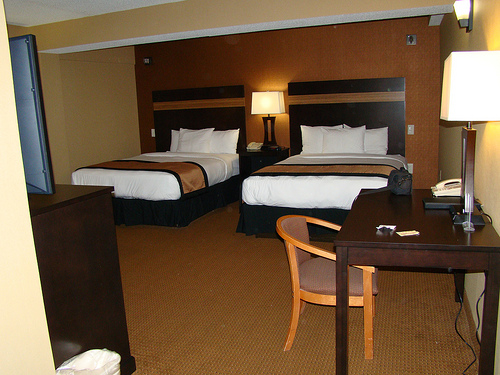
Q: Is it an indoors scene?
A: Yes, it is indoors.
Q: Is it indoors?
A: Yes, it is indoors.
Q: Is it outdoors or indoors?
A: It is indoors.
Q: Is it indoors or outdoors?
A: It is indoors.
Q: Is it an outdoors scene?
A: No, it is indoors.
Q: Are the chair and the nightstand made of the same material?
A: Yes, both the chair and the nightstand are made of wood.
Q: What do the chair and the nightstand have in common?
A: The material, both the chair and the nightstand are wooden.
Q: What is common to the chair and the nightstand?
A: The material, both the chair and the nightstand are wooden.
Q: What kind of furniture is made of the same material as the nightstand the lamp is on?
A: The chair is made of the same material as the nightstand.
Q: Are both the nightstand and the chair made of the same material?
A: Yes, both the nightstand and the chair are made of wood.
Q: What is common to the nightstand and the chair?
A: The material, both the nightstand and the chair are wooden.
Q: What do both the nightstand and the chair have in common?
A: The material, both the nightstand and the chair are wooden.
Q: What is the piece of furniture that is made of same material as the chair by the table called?
A: The piece of furniture is a nightstand.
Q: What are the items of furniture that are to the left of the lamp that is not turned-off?
A: The pieces of furniture are beds.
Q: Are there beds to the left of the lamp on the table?
A: Yes, there are beds to the left of the lamp.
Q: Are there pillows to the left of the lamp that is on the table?
A: No, there are beds to the left of the lamp.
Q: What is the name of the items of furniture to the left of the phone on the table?
A: The pieces of furniture are beds.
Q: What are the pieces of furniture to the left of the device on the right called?
A: The pieces of furniture are beds.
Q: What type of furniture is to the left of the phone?
A: The pieces of furniture are beds.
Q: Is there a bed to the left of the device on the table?
A: Yes, there are beds to the left of the telephone.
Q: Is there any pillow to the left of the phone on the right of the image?
A: No, there are beds to the left of the phone.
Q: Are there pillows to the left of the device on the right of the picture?
A: No, there are beds to the left of the phone.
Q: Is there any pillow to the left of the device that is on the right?
A: No, there are beds to the left of the phone.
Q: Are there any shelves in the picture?
A: No, there are no shelves.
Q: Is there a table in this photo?
A: Yes, there is a table.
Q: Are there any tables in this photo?
A: Yes, there is a table.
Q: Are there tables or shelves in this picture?
A: Yes, there is a table.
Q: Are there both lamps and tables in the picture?
A: Yes, there are both a table and a lamp.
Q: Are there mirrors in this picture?
A: No, there are no mirrors.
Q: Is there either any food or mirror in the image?
A: No, there are no mirrors or food.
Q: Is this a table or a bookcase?
A: This is a table.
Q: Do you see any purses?
A: Yes, there is a purse.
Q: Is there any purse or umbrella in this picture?
A: Yes, there is a purse.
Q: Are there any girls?
A: No, there are no girls.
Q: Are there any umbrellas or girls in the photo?
A: No, there are no girls or umbrellas.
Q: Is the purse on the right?
A: Yes, the purse is on the right of the image.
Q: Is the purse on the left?
A: No, the purse is on the right of the image.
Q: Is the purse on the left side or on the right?
A: The purse is on the right of the image.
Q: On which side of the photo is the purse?
A: The purse is on the right of the image.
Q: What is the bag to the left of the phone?
A: The bag is a purse.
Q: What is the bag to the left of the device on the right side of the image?
A: The bag is a purse.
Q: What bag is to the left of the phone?
A: The bag is a purse.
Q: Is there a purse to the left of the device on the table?
A: Yes, there is a purse to the left of the phone.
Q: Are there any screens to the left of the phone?
A: No, there is a purse to the left of the phone.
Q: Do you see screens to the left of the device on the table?
A: No, there is a purse to the left of the phone.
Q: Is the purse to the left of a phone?
A: Yes, the purse is to the left of a phone.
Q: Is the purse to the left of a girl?
A: No, the purse is to the left of a phone.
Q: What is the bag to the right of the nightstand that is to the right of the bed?
A: The bag is a purse.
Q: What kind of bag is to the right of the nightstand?
A: The bag is a purse.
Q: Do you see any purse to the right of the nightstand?
A: Yes, there is a purse to the right of the nightstand.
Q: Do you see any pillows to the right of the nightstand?
A: No, there is a purse to the right of the nightstand.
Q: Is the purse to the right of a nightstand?
A: Yes, the purse is to the right of a nightstand.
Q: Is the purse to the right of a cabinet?
A: No, the purse is to the right of a nightstand.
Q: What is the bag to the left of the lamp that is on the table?
A: The bag is a purse.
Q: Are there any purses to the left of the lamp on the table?
A: Yes, there is a purse to the left of the lamp.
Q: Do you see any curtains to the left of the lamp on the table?
A: No, there is a purse to the left of the lamp.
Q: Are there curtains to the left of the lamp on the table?
A: No, there is a purse to the left of the lamp.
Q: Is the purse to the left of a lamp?
A: Yes, the purse is to the left of a lamp.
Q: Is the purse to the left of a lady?
A: No, the purse is to the left of a lamp.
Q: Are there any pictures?
A: No, there are no pictures.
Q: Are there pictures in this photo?
A: No, there are no pictures.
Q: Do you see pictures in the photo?
A: No, there are no pictures.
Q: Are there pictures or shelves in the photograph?
A: No, there are no pictures or shelves.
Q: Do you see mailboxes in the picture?
A: No, there are no mailboxes.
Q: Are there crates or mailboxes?
A: No, there are no mailboxes or crates.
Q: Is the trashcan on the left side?
A: Yes, the trashcan is on the left of the image.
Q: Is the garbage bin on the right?
A: No, the garbage bin is on the left of the image.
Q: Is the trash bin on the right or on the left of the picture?
A: The trash bin is on the left of the image.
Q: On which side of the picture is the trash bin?
A: The trash bin is on the left of the image.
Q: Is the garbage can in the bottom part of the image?
A: Yes, the garbage can is in the bottom of the image.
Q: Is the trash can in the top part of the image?
A: No, the trash can is in the bottom of the image.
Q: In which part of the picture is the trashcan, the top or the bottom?
A: The trashcan is in the bottom of the image.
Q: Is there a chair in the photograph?
A: Yes, there is a chair.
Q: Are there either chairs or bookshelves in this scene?
A: Yes, there is a chair.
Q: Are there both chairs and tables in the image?
A: Yes, there are both a chair and a table.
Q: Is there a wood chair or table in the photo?
A: Yes, there is a wood chair.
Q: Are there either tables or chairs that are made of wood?
A: Yes, the chair is made of wood.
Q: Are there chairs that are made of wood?
A: Yes, there is a chair that is made of wood.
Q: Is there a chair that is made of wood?
A: Yes, there is a chair that is made of wood.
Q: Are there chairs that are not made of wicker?
A: Yes, there is a chair that is made of wood.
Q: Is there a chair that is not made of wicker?
A: Yes, there is a chair that is made of wood.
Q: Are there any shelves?
A: No, there are no shelves.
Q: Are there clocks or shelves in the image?
A: No, there are no shelves or clocks.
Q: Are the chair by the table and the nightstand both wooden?
A: Yes, both the chair and the nightstand are wooden.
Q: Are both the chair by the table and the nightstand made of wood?
A: Yes, both the chair and the nightstand are made of wood.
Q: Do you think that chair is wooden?
A: Yes, the chair is wooden.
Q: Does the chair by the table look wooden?
A: Yes, the chair is wooden.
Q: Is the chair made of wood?
A: Yes, the chair is made of wood.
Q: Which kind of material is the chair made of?
A: The chair is made of wood.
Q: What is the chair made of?
A: The chair is made of wood.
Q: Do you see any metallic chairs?
A: No, there is a chair but it is wooden.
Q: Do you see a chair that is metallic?
A: No, there is a chair but it is wooden.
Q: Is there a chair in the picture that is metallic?
A: No, there is a chair but it is wooden.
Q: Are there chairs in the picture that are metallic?
A: No, there is a chair but it is wooden.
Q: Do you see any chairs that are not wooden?
A: No, there is a chair but it is wooden.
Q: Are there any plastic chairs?
A: No, there is a chair but it is made of wood.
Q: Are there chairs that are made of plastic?
A: No, there is a chair but it is made of wood.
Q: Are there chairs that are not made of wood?
A: No, there is a chair but it is made of wood.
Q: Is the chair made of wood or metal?
A: The chair is made of wood.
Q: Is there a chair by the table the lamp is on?
A: Yes, there is a chair by the table.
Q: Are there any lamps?
A: Yes, there is a lamp.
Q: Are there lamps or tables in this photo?
A: Yes, there is a lamp.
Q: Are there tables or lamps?
A: Yes, there is a lamp.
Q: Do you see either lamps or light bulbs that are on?
A: Yes, the lamp is on.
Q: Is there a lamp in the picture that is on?
A: Yes, there is a lamp that is on.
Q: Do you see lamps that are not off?
A: Yes, there is a lamp that is on .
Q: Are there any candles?
A: No, there are no candles.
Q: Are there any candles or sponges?
A: No, there are no candles or sponges.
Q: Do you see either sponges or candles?
A: No, there are no candles or sponges.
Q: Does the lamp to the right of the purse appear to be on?
A: Yes, the lamp is on.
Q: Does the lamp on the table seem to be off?
A: No, the lamp is on.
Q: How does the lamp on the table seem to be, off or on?
A: The lamp is on.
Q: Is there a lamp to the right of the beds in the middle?
A: Yes, there is a lamp to the right of the beds.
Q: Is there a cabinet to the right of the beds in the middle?
A: No, there is a lamp to the right of the beds.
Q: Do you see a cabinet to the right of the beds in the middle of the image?
A: No, there is a lamp to the right of the beds.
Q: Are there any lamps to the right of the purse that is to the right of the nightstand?
A: Yes, there is a lamp to the right of the purse.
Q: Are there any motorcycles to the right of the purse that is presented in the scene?
A: No, there is a lamp to the right of the purse.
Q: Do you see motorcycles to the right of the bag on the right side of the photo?
A: No, there is a lamp to the right of the purse.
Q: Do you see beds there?
A: Yes, there is a bed.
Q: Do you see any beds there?
A: Yes, there is a bed.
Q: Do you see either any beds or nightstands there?
A: Yes, there is a bed.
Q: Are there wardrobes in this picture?
A: No, there are no wardrobes.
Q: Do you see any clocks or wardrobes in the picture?
A: No, there are no wardrobes or clocks.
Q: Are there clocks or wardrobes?
A: No, there are no wardrobes or clocks.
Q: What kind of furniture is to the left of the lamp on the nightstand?
A: The piece of furniture is a bed.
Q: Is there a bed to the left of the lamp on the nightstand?
A: Yes, there is a bed to the left of the lamp.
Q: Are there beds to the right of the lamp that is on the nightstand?
A: No, the bed is to the left of the lamp.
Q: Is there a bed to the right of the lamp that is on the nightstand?
A: No, the bed is to the left of the lamp.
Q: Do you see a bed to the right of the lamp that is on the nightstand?
A: No, the bed is to the left of the lamp.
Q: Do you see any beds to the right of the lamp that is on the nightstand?
A: No, the bed is to the left of the lamp.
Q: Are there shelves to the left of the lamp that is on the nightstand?
A: No, there is a bed to the left of the lamp.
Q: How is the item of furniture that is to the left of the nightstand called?
A: The piece of furniture is a bed.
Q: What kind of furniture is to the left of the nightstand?
A: The piece of furniture is a bed.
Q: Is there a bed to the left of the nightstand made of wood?
A: Yes, there is a bed to the left of the nightstand.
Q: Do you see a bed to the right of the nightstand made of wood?
A: No, the bed is to the left of the nightstand.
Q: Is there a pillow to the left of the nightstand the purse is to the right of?
A: No, there is a bed to the left of the nightstand.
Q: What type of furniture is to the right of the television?
A: The piece of furniture is a bed.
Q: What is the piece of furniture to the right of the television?
A: The piece of furniture is a bed.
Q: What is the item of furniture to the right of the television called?
A: The piece of furniture is a bed.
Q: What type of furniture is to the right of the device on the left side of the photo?
A: The piece of furniture is a bed.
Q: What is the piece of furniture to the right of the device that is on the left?
A: The piece of furniture is a bed.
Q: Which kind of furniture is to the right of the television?
A: The piece of furniture is a bed.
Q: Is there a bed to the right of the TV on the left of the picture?
A: Yes, there is a bed to the right of the television.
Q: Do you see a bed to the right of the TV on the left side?
A: Yes, there is a bed to the right of the television.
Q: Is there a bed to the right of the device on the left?
A: Yes, there is a bed to the right of the television.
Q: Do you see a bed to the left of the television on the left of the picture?
A: No, the bed is to the right of the TV.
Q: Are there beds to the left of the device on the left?
A: No, the bed is to the right of the TV.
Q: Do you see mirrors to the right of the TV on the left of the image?
A: No, there is a bed to the right of the television.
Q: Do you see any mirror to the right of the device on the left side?
A: No, there is a bed to the right of the television.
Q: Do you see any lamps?
A: Yes, there is a lamp.